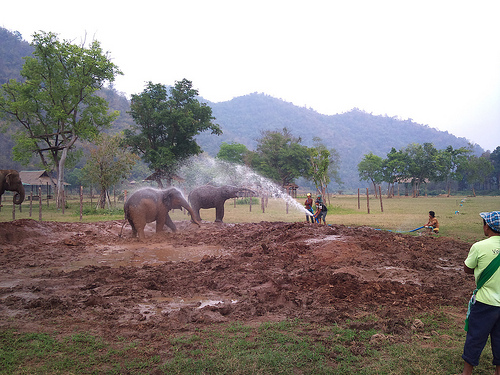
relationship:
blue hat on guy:
[477, 210, 499, 230] [457, 208, 500, 375]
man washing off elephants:
[298, 186, 352, 218] [85, 167, 286, 234]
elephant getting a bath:
[119, 183, 201, 242] [117, 152, 330, 235]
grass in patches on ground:
[5, 318, 493, 375] [2, 190, 497, 372]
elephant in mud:
[119, 183, 201, 242] [17, 214, 469, 354]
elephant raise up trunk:
[119, 183, 201, 242] [239, 183, 268, 198]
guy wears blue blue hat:
[457, 208, 500, 375] [477, 209, 499, 233]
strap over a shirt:
[474, 255, 499, 295] [453, 235, 498, 301]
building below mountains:
[12, 152, 76, 219] [80, 24, 475, 177]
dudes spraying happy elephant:
[255, 169, 353, 237] [107, 160, 324, 241]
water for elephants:
[174, 152, 313, 217] [121, 182, 255, 236]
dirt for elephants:
[4, 215, 476, 338] [121, 182, 255, 236]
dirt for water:
[4, 215, 476, 338] [174, 152, 313, 217]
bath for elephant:
[117, 152, 330, 235] [87, 179, 203, 245]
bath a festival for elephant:
[117, 152, 330, 235] [87, 179, 203, 245]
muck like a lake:
[9, 219, 480, 340] [57, 229, 266, 279]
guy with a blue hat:
[457, 211, 499, 359] [477, 209, 499, 233]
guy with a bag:
[457, 211, 499, 359] [456, 257, 498, 327]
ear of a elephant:
[160, 190, 172, 206] [115, 187, 202, 240]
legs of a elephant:
[155, 206, 176, 231] [119, 183, 203, 242]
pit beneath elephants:
[3, 235, 435, 316] [109, 139, 273, 261]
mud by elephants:
[0, 238, 459, 333] [113, 167, 249, 238]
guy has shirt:
[457, 208, 500, 375] [466, 235, 498, 307]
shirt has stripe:
[466, 235, 498, 307] [473, 263, 483, 296]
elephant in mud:
[119, 183, 203, 242] [104, 240, 217, 290]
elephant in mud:
[179, 168, 275, 233] [175, 215, 354, 285]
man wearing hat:
[303, 192, 314, 224] [302, 189, 314, 200]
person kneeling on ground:
[417, 206, 469, 253] [385, 195, 424, 228]